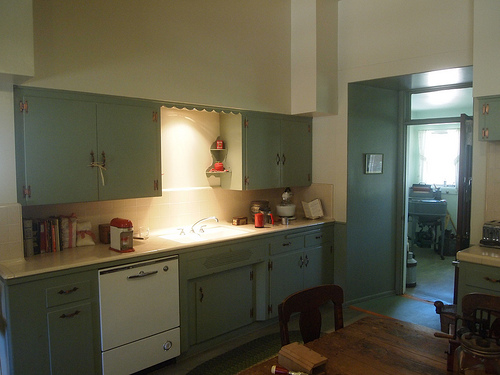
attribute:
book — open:
[299, 196, 326, 224]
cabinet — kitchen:
[45, 258, 95, 365]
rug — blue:
[190, 327, 329, 374]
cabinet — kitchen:
[19, 87, 104, 204]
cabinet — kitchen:
[180, 233, 288, 330]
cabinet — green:
[14, 82, 164, 211]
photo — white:
[361, 152, 385, 174]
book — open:
[302, 198, 322, 219]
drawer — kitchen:
[269, 229, 339, 315]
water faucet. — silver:
[160, 204, 261, 264]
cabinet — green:
[12, 85, 163, 203]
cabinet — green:
[219, 110, 313, 190]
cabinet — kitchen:
[90, 256, 187, 374]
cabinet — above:
[238, 116, 315, 189]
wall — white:
[1, 0, 497, 245]